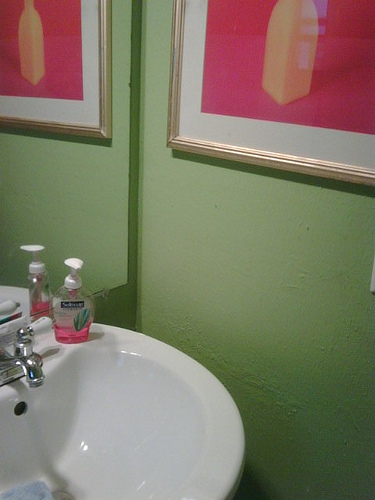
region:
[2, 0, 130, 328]
the mirror on the wall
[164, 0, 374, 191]
the picture hanging on the wall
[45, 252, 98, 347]
the soap on the sink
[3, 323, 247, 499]
the sink is white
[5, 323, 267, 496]
the sink is ceramic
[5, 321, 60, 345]
the handle of the faucet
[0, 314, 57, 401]
the faucet on the sink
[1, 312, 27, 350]
the toothpaste on the sink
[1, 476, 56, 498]
object in the sink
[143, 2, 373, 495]
the wall is green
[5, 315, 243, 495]
A white bathroom sink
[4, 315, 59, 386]
A chrome faucet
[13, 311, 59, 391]
A chrome faucet with a white handle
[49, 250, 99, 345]
A bottle of handsoap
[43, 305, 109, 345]
Pink handsoap in bottle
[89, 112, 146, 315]
A large mirror on wall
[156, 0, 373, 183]
A large pink picture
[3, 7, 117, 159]
A mirror image of a picture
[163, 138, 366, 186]
A gold colored frame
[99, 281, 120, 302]
A mirror clip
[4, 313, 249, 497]
the sink is white in color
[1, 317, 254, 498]
the sink is made of ceramic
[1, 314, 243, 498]
the sink is against the wall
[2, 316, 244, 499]
the sink is shiny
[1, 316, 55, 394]
the faucet is made of metal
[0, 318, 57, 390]
the faucet is shiny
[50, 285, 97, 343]
the bottle is made of plastic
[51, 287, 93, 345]
the bottle is transparent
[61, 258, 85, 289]
the cap is white in color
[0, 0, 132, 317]
A large mirror on a wall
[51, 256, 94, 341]
A small soap bottle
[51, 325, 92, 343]
some pink soap in a bottle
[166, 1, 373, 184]
A picture on the wall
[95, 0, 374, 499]
A green wall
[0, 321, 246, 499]
A small white sink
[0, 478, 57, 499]
A blue cloth in the sink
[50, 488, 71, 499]
A drain in the sink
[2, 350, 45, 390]
The faucet of a sink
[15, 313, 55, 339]
The handle of a sink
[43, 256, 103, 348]
soap bottle on sink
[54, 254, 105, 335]
pink soap in bottle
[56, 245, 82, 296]
white plunger on bottle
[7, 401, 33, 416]
small air hole in sink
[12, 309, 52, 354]
white handle on sink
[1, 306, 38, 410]
chrome faucet on sink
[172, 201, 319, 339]
green wall near sink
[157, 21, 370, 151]
picture hung on wall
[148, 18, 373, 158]
picture has bronze frame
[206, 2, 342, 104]
pink and yellow picture in frame